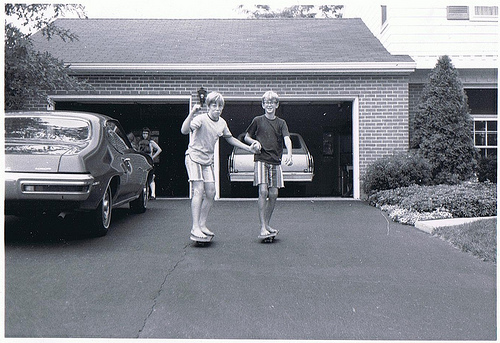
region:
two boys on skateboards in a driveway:
[180, 89, 293, 244]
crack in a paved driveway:
[138, 237, 191, 337]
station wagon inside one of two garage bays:
[217, 93, 360, 199]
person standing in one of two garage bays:
[48, 95, 194, 203]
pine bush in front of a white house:
[410, 53, 479, 183]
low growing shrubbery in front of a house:
[371, 182, 493, 222]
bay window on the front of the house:
[463, 114, 495, 154]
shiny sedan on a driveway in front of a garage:
[8, 106, 157, 234]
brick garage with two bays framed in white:
[7, 73, 411, 193]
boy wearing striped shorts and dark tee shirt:
[244, 90, 294, 233]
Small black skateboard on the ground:
[189, 228, 218, 248]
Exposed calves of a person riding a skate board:
[255, 183, 282, 240]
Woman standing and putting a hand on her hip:
[136, 123, 164, 173]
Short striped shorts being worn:
[181, 140, 221, 191]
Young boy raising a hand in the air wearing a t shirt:
[171, 83, 254, 160]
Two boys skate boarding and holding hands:
[178, 85, 296, 250]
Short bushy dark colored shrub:
[371, 147, 428, 187]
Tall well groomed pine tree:
[408, 47, 477, 182]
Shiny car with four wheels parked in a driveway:
[3, 106, 153, 249]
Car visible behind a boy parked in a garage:
[219, 125, 316, 185]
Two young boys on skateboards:
[174, 85, 298, 254]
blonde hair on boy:
[201, 91, 225, 101]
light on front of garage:
[198, 84, 207, 104]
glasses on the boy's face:
[263, 98, 273, 105]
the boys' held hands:
[246, 137, 263, 159]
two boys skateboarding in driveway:
[178, 86, 306, 266]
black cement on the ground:
[209, 255, 484, 340]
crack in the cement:
[139, 242, 192, 329]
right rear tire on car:
[90, 185, 115, 232]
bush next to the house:
[412, 75, 474, 171]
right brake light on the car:
[24, 182, 87, 196]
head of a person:
[179, 78, 237, 128]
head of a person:
[250, 85, 287, 116]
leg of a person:
[153, 166, 237, 257]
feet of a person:
[187, 222, 225, 243]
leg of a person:
[240, 173, 272, 240]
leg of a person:
[265, 169, 292, 223]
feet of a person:
[250, 221, 295, 241]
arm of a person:
[222, 126, 252, 156]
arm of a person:
[237, 128, 269, 152]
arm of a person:
[266, 115, 311, 156]